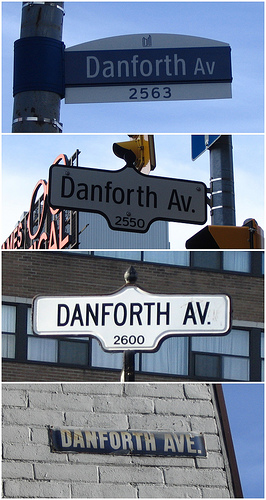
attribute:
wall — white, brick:
[1, 381, 233, 498]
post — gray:
[14, 1, 63, 134]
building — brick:
[1, 252, 263, 381]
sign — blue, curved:
[65, 34, 234, 104]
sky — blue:
[222, 382, 260, 499]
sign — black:
[45, 426, 207, 460]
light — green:
[114, 142, 136, 165]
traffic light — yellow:
[111, 132, 158, 173]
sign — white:
[49, 161, 208, 235]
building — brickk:
[3, 384, 235, 499]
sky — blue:
[0, 132, 263, 251]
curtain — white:
[93, 342, 126, 369]